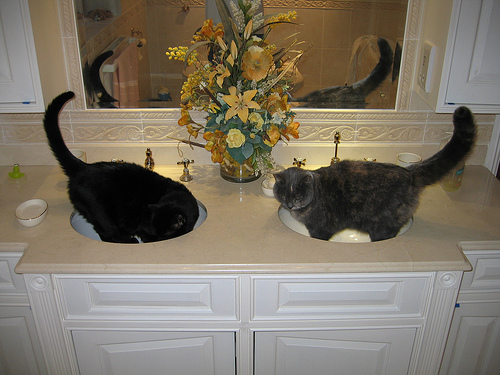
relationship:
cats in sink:
[32, 96, 472, 244] [297, 197, 431, 255]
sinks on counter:
[71, 180, 410, 249] [45, 152, 491, 274]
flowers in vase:
[185, 12, 285, 123] [195, 125, 267, 193]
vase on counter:
[195, 125, 267, 193] [45, 152, 491, 274]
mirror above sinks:
[56, 7, 403, 103] [71, 180, 410, 249]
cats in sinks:
[32, 96, 472, 244] [71, 180, 410, 249]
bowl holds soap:
[21, 207, 49, 226] [24, 191, 41, 222]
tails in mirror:
[85, 46, 401, 96] [56, 7, 403, 103]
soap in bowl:
[24, 191, 41, 222] [21, 207, 49, 226]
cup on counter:
[261, 173, 279, 191] [45, 152, 491, 274]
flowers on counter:
[185, 12, 285, 123] [45, 152, 491, 274]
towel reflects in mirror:
[118, 36, 144, 97] [56, 7, 403, 103]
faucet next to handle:
[331, 129, 345, 160] [291, 154, 305, 168]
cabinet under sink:
[62, 273, 420, 367] [297, 197, 431, 255]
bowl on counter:
[21, 207, 49, 226] [45, 152, 491, 274]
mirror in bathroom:
[56, 7, 403, 103] [8, 10, 491, 374]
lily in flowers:
[214, 90, 262, 124] [185, 12, 285, 123]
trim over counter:
[56, 114, 418, 162] [45, 152, 491, 274]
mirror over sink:
[56, 7, 403, 103] [297, 197, 431, 255]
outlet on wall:
[414, 41, 431, 98] [414, 2, 448, 120]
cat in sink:
[277, 105, 490, 250] [297, 197, 431, 255]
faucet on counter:
[331, 129, 345, 160] [45, 152, 491, 274]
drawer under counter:
[257, 279, 426, 315] [45, 152, 491, 274]